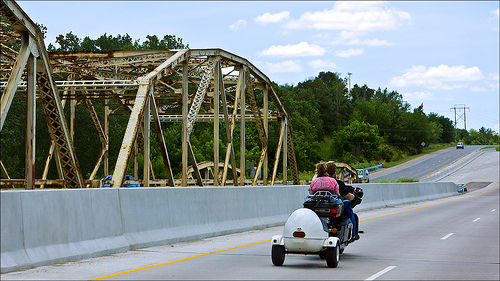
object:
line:
[364, 208, 500, 281]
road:
[0, 144, 500, 279]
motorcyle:
[303, 186, 365, 260]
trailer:
[270, 208, 340, 268]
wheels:
[271, 244, 286, 267]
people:
[307, 161, 355, 238]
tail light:
[293, 231, 306, 237]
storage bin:
[302, 196, 344, 218]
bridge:
[1, 0, 298, 192]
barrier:
[0, 182, 460, 273]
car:
[457, 142, 465, 149]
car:
[356, 168, 370, 182]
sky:
[15, 0, 498, 133]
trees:
[2, 20, 500, 180]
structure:
[450, 104, 471, 131]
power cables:
[455, 113, 465, 122]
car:
[100, 175, 141, 189]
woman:
[309, 162, 340, 197]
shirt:
[310, 175, 339, 194]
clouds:
[231, 2, 412, 56]